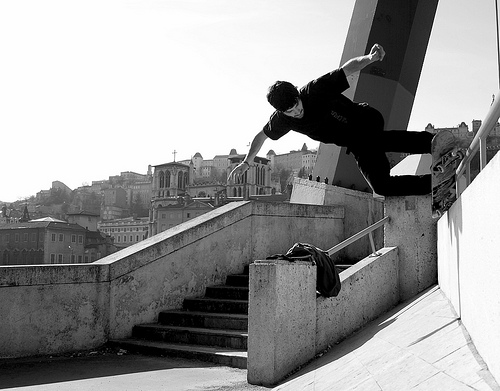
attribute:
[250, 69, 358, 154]
shirt — black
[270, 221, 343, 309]
sweater — black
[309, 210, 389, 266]
rail — hand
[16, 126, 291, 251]
buildings — old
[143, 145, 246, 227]
building — old, church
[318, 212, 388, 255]
rail — metal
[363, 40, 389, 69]
left hand — up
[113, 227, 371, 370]
stairs — pictured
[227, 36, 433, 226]
man — trick-performing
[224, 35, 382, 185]
arms — extended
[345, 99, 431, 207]
pants — dark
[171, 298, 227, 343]
stairs — set